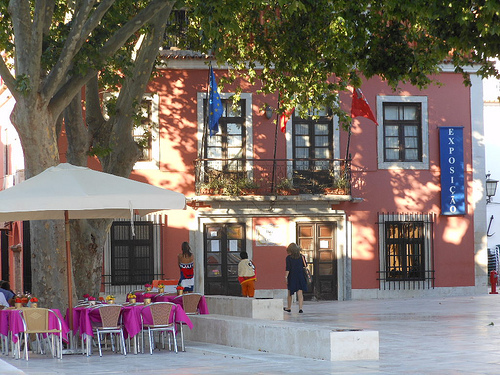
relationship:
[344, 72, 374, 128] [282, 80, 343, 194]
flag to right of door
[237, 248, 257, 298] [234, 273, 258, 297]
woman wearing pants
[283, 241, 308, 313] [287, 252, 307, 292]
woman wearing dress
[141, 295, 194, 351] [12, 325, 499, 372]
chair on ground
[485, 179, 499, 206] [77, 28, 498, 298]
lamp in building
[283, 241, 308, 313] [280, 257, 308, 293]
woman in dress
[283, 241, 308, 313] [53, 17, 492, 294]
woman walking towards building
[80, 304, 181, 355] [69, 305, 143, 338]
tables with tablecloth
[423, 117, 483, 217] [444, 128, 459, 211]
banner with letters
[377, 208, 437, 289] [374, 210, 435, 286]
cage covering window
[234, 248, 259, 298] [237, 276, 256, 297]
woman in pants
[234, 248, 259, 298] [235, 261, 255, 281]
woman in shirt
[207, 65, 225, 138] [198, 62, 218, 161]
flag on pole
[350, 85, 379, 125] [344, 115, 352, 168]
flag on pole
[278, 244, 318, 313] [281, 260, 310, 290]
woman wearing dress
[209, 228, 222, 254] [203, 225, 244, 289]
paper on door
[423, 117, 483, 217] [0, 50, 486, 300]
banner on building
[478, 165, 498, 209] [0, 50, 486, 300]
lamp on building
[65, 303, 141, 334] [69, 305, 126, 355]
tablecloth on table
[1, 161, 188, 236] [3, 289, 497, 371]
umbrella on ground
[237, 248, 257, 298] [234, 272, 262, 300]
woman wearing pants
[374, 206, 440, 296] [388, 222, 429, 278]
gate on window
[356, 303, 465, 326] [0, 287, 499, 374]
shadow on walkway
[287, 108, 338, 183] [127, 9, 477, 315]
window on building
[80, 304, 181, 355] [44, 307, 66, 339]
tables covered by cloth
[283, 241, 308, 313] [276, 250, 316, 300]
woman wearing dress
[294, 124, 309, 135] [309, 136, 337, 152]
window with sections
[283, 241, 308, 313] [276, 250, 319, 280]
woman in dress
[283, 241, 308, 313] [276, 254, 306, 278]
woman in dress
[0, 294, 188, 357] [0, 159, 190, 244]
tables under a gazibo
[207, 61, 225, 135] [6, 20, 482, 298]
flag on front of building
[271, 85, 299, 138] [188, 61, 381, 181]
flag in middle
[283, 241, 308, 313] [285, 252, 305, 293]
woman in dress